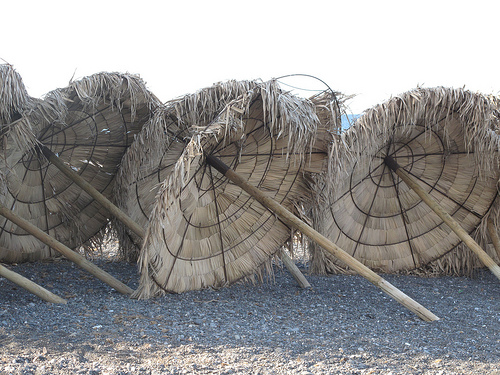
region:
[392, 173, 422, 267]
black support on umbrella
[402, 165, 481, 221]
black support on umbrella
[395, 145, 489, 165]
black support on umbrella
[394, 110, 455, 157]
black support on umbrella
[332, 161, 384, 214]
black support on umbrella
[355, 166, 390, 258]
black support on umbrella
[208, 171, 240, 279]
black support on umbrella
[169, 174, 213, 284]
black support on umbrella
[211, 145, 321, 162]
black support on umbrella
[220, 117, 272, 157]
black support on umbrella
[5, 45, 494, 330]
tents lined in a row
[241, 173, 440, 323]
wooden pole of the tent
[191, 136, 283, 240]
wired support under the covering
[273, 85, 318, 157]
grassy texture on top of tents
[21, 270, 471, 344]
ground tents rest on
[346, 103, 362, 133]
water behind the tents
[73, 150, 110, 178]
holes in the tent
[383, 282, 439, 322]
lighter colored end of pole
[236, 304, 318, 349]
rock and gravel on ground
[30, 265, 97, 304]
dirt on the ground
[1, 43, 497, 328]
MANY UMBRELLAS ARE TOGETHER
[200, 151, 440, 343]
THE POLE FOR THE UMBRELLA IS WOODEN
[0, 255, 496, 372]
THE GROUND IS COVERED WITH SMALL BLACK ROCKS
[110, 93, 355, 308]
THE GRASS USED TO MAKE THIS IS DRY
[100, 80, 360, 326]
THE UMBRELLA IS GRASS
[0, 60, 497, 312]
THE UMBRELLAS ARE ON THEIR SIDES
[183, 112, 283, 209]
THE FRAME OF THE UMBRELLA IS WIRE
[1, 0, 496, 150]
THE SKY IS BRIGHT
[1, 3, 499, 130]
THE SKY IS WHITE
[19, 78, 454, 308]
three large umbrellas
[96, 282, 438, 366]
sand on a beach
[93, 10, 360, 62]
clear bright sky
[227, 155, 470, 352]
posts on beach umbrellas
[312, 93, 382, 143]
ocean behind a beach umbrella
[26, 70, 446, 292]
umbrellas laying on the beach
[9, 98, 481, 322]
five beach posts on umbrellas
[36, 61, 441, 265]
hand made umbrellas on the ground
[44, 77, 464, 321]
umbrellas in the sand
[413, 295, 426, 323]
part of a board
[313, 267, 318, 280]
part of a surface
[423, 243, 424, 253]
part of an umbrella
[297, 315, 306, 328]
part of a floor